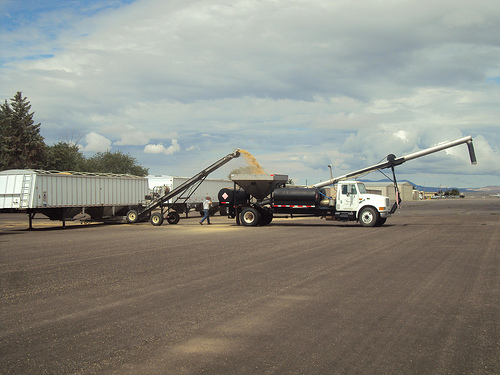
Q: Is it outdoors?
A: Yes, it is outdoors.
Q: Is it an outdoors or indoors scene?
A: It is outdoors.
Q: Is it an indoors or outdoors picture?
A: It is outdoors.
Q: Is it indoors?
A: No, it is outdoors.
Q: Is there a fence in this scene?
A: No, there are no fences.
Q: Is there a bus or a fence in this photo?
A: No, there are no fences or buses.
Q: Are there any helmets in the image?
A: No, there are no helmets.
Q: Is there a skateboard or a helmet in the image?
A: No, there are no helmets or skateboards.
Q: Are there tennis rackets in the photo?
A: No, there are no tennis rackets.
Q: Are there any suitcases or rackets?
A: No, there are no rackets or suitcases.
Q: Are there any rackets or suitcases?
A: No, there are no rackets or suitcases.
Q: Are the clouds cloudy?
A: Yes, the clouds are cloudy.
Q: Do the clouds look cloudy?
A: Yes, the clouds are cloudy.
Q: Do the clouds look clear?
A: No, the clouds are cloudy.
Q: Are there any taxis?
A: Yes, there is a taxi.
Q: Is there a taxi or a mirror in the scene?
A: Yes, there is a taxi.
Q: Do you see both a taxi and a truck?
A: Yes, there are both a taxi and a truck.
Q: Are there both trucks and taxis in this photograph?
A: Yes, there are both a taxi and a truck.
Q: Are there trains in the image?
A: No, there are no trains.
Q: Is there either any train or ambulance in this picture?
A: No, there are no trains or ambulances.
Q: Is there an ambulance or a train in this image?
A: No, there are no trains or ambulances.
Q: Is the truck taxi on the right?
A: Yes, the cab is on the right of the image.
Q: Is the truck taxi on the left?
A: No, the taxi is on the right of the image.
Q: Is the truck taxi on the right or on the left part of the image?
A: The cab is on the right of the image.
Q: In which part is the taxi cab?
A: The taxi cab is on the right of the image.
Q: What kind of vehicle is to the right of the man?
A: The vehicle is a taxi.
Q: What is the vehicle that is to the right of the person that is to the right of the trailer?
A: The vehicle is a taxi.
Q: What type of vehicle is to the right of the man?
A: The vehicle is a taxi.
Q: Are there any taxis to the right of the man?
A: Yes, there is a taxi to the right of the man.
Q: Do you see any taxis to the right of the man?
A: Yes, there is a taxi to the right of the man.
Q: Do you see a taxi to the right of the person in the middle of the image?
A: Yes, there is a taxi to the right of the man.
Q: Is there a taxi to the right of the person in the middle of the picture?
A: Yes, there is a taxi to the right of the man.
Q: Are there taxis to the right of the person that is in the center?
A: Yes, there is a taxi to the right of the man.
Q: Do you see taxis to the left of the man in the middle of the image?
A: No, the taxi is to the right of the man.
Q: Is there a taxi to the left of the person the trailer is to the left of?
A: No, the taxi is to the right of the man.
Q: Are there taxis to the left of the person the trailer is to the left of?
A: No, the taxi is to the right of the man.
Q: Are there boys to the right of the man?
A: No, there is a taxi to the right of the man.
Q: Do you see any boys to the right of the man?
A: No, there is a taxi to the right of the man.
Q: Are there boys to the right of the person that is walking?
A: No, there is a taxi to the right of the man.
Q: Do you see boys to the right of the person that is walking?
A: No, there is a taxi to the right of the man.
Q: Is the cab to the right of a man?
A: Yes, the cab is to the right of a man.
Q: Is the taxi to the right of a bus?
A: No, the taxi is to the right of a man.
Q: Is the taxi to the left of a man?
A: No, the taxi is to the right of a man.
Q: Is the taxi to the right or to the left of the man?
A: The taxi is to the right of the man.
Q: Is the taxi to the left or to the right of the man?
A: The taxi is to the right of the man.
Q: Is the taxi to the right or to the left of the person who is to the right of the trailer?
A: The taxi is to the right of the man.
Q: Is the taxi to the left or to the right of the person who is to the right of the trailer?
A: The taxi is to the right of the man.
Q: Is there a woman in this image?
A: No, there are no women.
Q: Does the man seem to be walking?
A: Yes, the man is walking.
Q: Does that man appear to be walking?
A: Yes, the man is walking.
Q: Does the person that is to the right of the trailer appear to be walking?
A: Yes, the man is walking.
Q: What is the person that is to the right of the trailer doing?
A: The man is walking.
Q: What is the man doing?
A: The man is walking.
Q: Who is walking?
A: The man is walking.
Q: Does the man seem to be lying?
A: No, the man is walking.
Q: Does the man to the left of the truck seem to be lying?
A: No, the man is walking.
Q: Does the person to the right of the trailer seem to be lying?
A: No, the man is walking.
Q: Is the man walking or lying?
A: The man is walking.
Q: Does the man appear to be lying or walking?
A: The man is walking.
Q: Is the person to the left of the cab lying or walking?
A: The man is walking.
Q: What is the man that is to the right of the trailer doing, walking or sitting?
A: The man is walking.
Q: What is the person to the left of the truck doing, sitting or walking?
A: The man is walking.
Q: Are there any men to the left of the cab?
A: Yes, there is a man to the left of the cab.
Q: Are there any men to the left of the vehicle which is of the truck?
A: Yes, there is a man to the left of the cab.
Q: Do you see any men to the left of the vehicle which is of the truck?
A: Yes, there is a man to the left of the cab.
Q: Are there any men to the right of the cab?
A: No, the man is to the left of the cab.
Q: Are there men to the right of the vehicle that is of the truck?
A: No, the man is to the left of the cab.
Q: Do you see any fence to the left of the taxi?
A: No, there is a man to the left of the taxi.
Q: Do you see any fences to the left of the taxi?
A: No, there is a man to the left of the taxi.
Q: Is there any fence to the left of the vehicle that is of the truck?
A: No, there is a man to the left of the taxi.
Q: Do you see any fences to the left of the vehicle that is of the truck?
A: No, there is a man to the left of the taxi.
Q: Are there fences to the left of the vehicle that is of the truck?
A: No, there is a man to the left of the taxi.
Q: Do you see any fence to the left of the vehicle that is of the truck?
A: No, there is a man to the left of the taxi.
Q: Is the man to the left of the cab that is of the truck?
A: Yes, the man is to the left of the cab.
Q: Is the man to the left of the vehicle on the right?
A: Yes, the man is to the left of the cab.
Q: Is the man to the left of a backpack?
A: No, the man is to the left of the cab.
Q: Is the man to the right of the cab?
A: No, the man is to the left of the cab.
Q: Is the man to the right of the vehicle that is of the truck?
A: No, the man is to the left of the cab.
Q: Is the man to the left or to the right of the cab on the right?
A: The man is to the left of the taxi.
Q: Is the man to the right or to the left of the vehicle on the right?
A: The man is to the left of the taxi.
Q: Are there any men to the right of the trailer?
A: Yes, there is a man to the right of the trailer.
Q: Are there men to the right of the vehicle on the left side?
A: Yes, there is a man to the right of the trailer.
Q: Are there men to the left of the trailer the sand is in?
A: No, the man is to the right of the trailer.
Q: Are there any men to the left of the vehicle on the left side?
A: No, the man is to the right of the trailer.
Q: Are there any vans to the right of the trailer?
A: No, there is a man to the right of the trailer.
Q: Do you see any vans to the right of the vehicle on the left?
A: No, there is a man to the right of the trailer.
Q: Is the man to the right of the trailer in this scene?
A: Yes, the man is to the right of the trailer.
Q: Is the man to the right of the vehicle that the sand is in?
A: Yes, the man is to the right of the trailer.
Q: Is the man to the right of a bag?
A: No, the man is to the right of the trailer.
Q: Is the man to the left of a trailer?
A: No, the man is to the right of a trailer.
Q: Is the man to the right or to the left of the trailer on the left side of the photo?
A: The man is to the right of the trailer.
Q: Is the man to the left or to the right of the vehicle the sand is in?
A: The man is to the right of the trailer.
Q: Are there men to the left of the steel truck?
A: Yes, there is a man to the left of the truck.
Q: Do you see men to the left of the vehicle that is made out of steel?
A: Yes, there is a man to the left of the truck.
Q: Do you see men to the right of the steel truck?
A: No, the man is to the left of the truck.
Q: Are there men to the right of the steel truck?
A: No, the man is to the left of the truck.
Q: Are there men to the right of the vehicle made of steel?
A: No, the man is to the left of the truck.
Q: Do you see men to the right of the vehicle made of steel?
A: No, the man is to the left of the truck.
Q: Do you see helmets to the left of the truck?
A: No, there is a man to the left of the truck.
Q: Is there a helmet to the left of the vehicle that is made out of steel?
A: No, there is a man to the left of the truck.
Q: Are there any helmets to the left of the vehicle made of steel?
A: No, there is a man to the left of the truck.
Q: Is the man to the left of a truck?
A: Yes, the man is to the left of a truck.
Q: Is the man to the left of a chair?
A: No, the man is to the left of a truck.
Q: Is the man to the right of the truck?
A: No, the man is to the left of the truck.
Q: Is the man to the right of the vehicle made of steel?
A: No, the man is to the left of the truck.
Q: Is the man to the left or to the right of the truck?
A: The man is to the left of the truck.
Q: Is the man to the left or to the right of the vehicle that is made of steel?
A: The man is to the left of the truck.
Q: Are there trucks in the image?
A: Yes, there is a truck.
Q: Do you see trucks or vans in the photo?
A: Yes, there is a truck.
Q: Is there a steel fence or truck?
A: Yes, there is a steel truck.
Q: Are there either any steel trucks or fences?
A: Yes, there is a steel truck.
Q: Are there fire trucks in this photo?
A: No, there are no fire trucks.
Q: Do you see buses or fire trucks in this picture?
A: No, there are no fire trucks or buses.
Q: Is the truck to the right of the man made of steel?
A: Yes, the truck is made of steel.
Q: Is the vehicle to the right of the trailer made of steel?
A: Yes, the truck is made of steel.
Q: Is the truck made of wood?
A: No, the truck is made of steel.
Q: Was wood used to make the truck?
A: No, the truck is made of steel.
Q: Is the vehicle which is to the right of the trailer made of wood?
A: No, the truck is made of steel.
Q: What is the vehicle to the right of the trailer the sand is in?
A: The vehicle is a truck.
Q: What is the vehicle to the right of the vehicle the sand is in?
A: The vehicle is a truck.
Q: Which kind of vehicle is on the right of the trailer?
A: The vehicle is a truck.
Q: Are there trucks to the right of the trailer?
A: Yes, there is a truck to the right of the trailer.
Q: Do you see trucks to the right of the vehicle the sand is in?
A: Yes, there is a truck to the right of the trailer.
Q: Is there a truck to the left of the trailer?
A: No, the truck is to the right of the trailer.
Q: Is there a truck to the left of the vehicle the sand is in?
A: No, the truck is to the right of the trailer.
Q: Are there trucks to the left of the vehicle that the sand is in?
A: No, the truck is to the right of the trailer.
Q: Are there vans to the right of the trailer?
A: No, there is a truck to the right of the trailer.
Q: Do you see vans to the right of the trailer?
A: No, there is a truck to the right of the trailer.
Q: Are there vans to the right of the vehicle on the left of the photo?
A: No, there is a truck to the right of the trailer.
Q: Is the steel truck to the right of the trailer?
A: Yes, the truck is to the right of the trailer.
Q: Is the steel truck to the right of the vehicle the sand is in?
A: Yes, the truck is to the right of the trailer.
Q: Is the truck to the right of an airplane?
A: No, the truck is to the right of the trailer.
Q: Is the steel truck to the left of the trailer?
A: No, the truck is to the right of the trailer.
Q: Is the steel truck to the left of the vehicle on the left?
A: No, the truck is to the right of the trailer.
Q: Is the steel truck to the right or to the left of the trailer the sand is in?
A: The truck is to the right of the trailer.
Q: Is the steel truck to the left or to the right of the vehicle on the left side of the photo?
A: The truck is to the right of the trailer.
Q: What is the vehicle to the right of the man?
A: The vehicle is a truck.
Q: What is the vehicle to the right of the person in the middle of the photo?
A: The vehicle is a truck.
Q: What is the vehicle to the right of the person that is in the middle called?
A: The vehicle is a truck.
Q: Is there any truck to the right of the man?
A: Yes, there is a truck to the right of the man.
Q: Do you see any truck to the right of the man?
A: Yes, there is a truck to the right of the man.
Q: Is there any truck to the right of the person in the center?
A: Yes, there is a truck to the right of the man.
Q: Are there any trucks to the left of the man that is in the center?
A: No, the truck is to the right of the man.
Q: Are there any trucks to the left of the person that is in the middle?
A: No, the truck is to the right of the man.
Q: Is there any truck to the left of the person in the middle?
A: No, the truck is to the right of the man.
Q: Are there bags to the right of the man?
A: No, there is a truck to the right of the man.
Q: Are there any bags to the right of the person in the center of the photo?
A: No, there is a truck to the right of the man.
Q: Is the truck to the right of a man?
A: Yes, the truck is to the right of a man.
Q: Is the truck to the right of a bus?
A: No, the truck is to the right of a man.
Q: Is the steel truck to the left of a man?
A: No, the truck is to the right of a man.